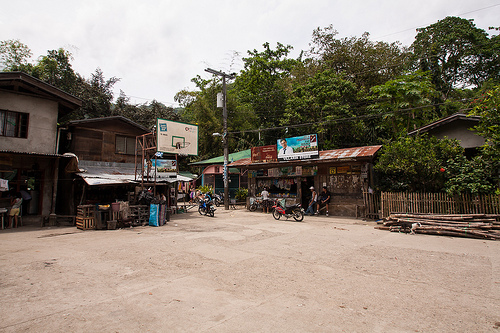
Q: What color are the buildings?
A: Brown.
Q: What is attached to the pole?
A: Basketball net.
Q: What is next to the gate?
A: Wood.